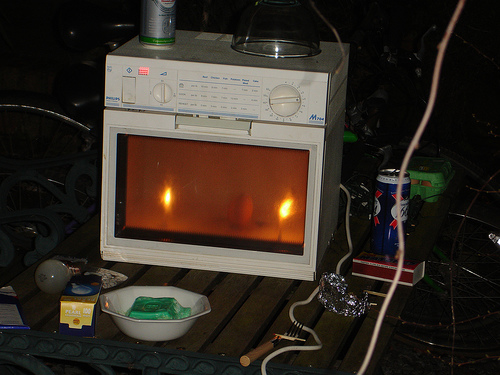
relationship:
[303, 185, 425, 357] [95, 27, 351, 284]
cord to appliance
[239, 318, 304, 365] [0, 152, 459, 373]
fork laying on counter(table)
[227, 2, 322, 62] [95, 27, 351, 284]
bowl on top of appliance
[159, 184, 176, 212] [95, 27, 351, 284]
flame in appliance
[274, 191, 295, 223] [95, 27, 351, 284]
flame in appliance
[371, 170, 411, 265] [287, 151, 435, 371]
beer can on slat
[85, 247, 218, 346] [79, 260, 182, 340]
bowl on slat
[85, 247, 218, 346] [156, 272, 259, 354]
bowl on slat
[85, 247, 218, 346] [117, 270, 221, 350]
bowl on slat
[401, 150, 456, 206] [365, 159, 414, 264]
box beside beer can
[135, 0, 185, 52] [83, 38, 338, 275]
beer on microwave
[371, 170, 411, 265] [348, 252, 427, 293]
beer can on match box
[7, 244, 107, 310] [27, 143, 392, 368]
lightbulb on table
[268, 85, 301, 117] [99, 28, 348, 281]
dial on appliance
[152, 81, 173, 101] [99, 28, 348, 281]
dial on appliance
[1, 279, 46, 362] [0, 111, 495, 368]
wrapper on table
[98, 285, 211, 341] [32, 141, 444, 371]
bowl on table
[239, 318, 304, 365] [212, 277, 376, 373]
fork on table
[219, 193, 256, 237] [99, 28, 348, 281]
egg in appliance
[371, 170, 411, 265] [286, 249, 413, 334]
beer can on table